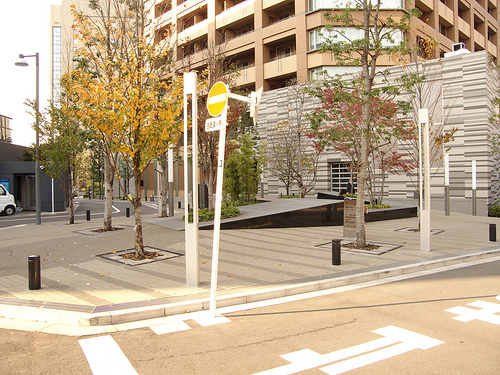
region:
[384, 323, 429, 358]
white paint on street.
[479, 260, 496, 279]
shadow on the street.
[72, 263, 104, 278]
shadow on the sidewalk.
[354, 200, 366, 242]
trunk of the tree.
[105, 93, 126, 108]
leaves on the tree.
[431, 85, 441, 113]
branches on the tree.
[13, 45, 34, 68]
light on the pole.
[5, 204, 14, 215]
wheel on the van.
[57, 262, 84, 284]
leaves on the ground.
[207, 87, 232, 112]
sign on the pole.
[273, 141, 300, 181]
the tree is bare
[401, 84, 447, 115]
the tree is bare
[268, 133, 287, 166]
the tree is bare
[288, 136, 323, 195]
the tree is bare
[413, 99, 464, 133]
the tree is bare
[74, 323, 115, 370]
white painted line on the floor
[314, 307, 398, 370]
white painted line on the floor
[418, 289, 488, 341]
white painted line on the floor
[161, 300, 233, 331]
white painted line on the floor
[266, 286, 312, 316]
white painted line on the floor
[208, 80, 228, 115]
The round reddish sign with the white dash through it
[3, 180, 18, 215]
The rear of a small white car on the left of the frame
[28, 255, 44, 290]
The short black pole on the left side of the photo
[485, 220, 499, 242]
The small black pole furthest to the right of the photo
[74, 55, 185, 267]
The tree with the primarily yellow leaves on it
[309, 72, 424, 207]
The tree with purplish flowers mixed in with the leaves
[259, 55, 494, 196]
The striped multi-toned gray exterior of a building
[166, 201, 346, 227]
The black concrete ramp in the middle of the sidewalk area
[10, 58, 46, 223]
The tall light fixture near the white car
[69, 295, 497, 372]
The white painted sections of the pavement nearest the camera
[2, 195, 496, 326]
corner of sidewalk near building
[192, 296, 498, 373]
street directions painted on street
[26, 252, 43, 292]
building protectors from cars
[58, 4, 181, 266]
one of trees planted in sidewalk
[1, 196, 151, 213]
adjasent street of sidewalk and building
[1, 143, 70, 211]
grey building across the street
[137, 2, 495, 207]
large tan building on corner sidwalk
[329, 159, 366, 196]
entrance to lobby of building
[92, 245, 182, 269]
derotive hole where tree is planted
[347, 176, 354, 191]
man walking out of building lobby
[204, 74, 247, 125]
a do not enter sign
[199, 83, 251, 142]
a wrong way sign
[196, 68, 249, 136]
the sign looks yellow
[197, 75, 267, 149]
the sign is shaped like a circle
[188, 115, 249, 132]
there are Asian characters in the sign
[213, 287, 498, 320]
the shadow of the sign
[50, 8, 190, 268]
the leaves of the tree are yellow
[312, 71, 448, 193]
the leaves are red and green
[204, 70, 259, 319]
a tall street sign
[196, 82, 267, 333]
the sign post is white